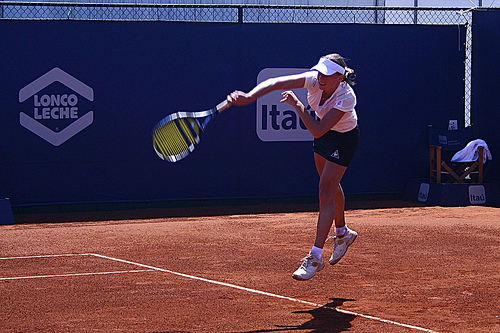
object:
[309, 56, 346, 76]
visor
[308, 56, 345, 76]
white visor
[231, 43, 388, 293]
woman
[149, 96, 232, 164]
tennis racket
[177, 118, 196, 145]
net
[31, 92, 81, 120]
loncho leche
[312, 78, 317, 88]
logo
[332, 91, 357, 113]
sleeve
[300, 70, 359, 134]
tee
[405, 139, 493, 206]
chair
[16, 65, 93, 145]
logo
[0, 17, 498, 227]
barrier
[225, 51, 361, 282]
female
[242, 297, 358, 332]
shadow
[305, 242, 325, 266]
sock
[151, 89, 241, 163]
racket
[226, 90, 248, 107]
hand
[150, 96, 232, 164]
tennis rack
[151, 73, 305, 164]
backhand swing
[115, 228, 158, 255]
dirt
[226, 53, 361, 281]
woman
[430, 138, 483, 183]
chair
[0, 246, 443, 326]
tennis courts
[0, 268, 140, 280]
line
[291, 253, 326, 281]
left shoe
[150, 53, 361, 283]
tennis player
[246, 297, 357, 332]
shadow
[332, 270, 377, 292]
ground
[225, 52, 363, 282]
person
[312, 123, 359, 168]
shorts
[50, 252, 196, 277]
lines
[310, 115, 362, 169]
black shorts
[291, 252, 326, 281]
shoe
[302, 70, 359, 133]
shirt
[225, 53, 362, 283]
player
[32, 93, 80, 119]
word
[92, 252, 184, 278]
line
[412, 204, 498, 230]
pavement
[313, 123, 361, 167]
skirt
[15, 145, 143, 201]
wall